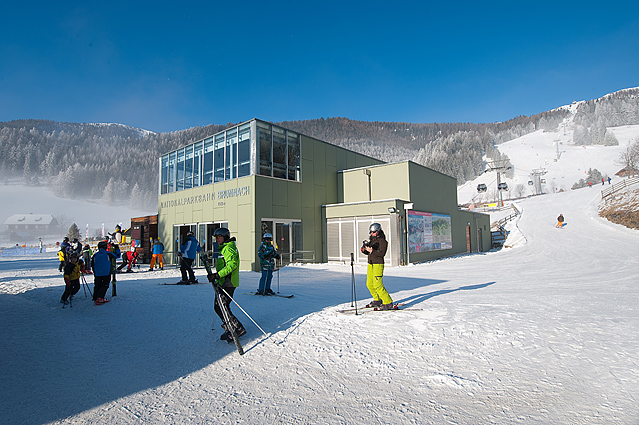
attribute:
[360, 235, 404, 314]
ski gear — yellow, black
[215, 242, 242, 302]
coat — lime green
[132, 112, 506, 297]
ski lodge — light grey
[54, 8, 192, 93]
skies — Large 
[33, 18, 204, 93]
skies — Large 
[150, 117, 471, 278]
building — tan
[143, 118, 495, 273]
building — windows 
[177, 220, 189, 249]
building — door 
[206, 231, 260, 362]
person — green jacket 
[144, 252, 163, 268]
pants — orange ski 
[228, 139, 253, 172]
glass — clean, clear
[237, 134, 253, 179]
glass — clear, clean 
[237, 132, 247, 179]
glass — clean , clear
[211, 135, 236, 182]
glass — clear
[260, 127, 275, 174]
glass — clear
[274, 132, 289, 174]
glass — clear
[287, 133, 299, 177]
glass — clear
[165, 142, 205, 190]
glass — clear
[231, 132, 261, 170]
glass — clear